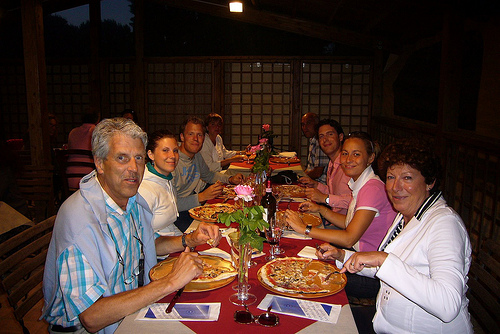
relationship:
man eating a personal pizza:
[38, 115, 224, 333] [158, 254, 237, 284]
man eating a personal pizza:
[175, 113, 246, 204] [214, 181, 247, 198]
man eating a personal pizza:
[294, 106, 328, 178] [275, 151, 302, 166]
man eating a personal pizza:
[299, 118, 352, 206] [274, 181, 312, 201]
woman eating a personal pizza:
[144, 131, 195, 251] [189, 202, 240, 223]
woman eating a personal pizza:
[203, 113, 250, 171] [241, 150, 259, 160]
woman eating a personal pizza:
[286, 130, 399, 252] [275, 207, 321, 229]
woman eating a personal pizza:
[311, 140, 477, 333] [259, 256, 347, 304]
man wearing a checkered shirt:
[38, 115, 224, 333] [43, 189, 164, 329]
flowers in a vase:
[216, 180, 269, 285] [231, 242, 266, 306]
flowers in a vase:
[253, 138, 274, 184] [252, 169, 266, 205]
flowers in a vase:
[261, 123, 274, 145] [268, 141, 271, 161]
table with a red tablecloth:
[112, 150, 363, 334] [157, 230, 350, 333]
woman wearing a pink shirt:
[286, 130, 399, 252] [340, 178, 397, 254]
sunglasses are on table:
[232, 308, 280, 331] [112, 150, 363, 334]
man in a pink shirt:
[299, 118, 352, 206] [309, 156, 356, 208]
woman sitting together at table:
[313, 140, 477, 333] [112, 150, 363, 334]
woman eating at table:
[313, 140, 477, 333] [112, 150, 363, 334]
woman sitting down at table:
[313, 140, 477, 333] [112, 150, 363, 334]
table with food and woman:
[112, 150, 363, 334] [313, 140, 477, 333]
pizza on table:
[158, 254, 237, 284] [112, 150, 363, 334]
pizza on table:
[189, 202, 240, 223] [112, 150, 363, 334]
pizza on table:
[214, 181, 247, 198] [112, 150, 363, 334]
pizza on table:
[259, 256, 347, 304] [112, 150, 363, 334]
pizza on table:
[274, 181, 312, 201] [112, 150, 363, 334]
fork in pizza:
[324, 267, 364, 280] [259, 256, 347, 304]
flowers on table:
[216, 180, 269, 285] [112, 150, 363, 334]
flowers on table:
[253, 138, 274, 184] [112, 150, 363, 334]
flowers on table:
[261, 123, 274, 145] [112, 150, 363, 334]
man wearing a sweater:
[38, 115, 224, 333] [48, 170, 160, 326]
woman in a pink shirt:
[286, 130, 399, 252] [340, 178, 397, 254]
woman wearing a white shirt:
[203, 113, 250, 171] [194, 134, 236, 168]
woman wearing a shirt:
[286, 130, 399, 252] [340, 178, 397, 254]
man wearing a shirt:
[299, 118, 352, 206] [309, 156, 356, 208]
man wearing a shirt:
[38, 115, 224, 333] [43, 189, 164, 329]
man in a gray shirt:
[175, 113, 246, 204] [172, 150, 234, 209]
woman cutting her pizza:
[311, 140, 477, 333] [259, 256, 347, 304]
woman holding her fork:
[311, 140, 477, 333] [324, 267, 364, 280]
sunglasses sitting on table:
[232, 308, 280, 331] [112, 150, 363, 334]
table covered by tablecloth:
[112, 150, 363, 334] [157, 230, 350, 333]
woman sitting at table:
[313, 140, 477, 333] [112, 150, 363, 334]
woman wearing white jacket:
[311, 140, 477, 333] [340, 203, 478, 334]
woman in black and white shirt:
[311, 140, 477, 333] [43, 189, 164, 329]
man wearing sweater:
[38, 115, 224, 333] [48, 170, 160, 326]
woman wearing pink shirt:
[286, 130, 399, 252] [340, 178, 397, 254]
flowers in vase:
[216, 180, 269, 285] [231, 242, 266, 306]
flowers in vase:
[253, 138, 274, 184] [252, 169, 266, 205]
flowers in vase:
[261, 123, 274, 145] [268, 141, 271, 161]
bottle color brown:
[259, 179, 276, 232] [265, 196, 271, 202]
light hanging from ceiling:
[226, 0, 248, 17] [193, 0, 498, 7]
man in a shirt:
[299, 118, 352, 206] [43, 189, 164, 329]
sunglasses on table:
[232, 308, 280, 331] [112, 150, 363, 334]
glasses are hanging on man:
[114, 228, 146, 282] [38, 115, 224, 333]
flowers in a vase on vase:
[216, 180, 269, 285] [231, 242, 266, 306]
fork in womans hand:
[324, 267, 364, 280] [341, 246, 387, 278]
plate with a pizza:
[152, 253, 238, 295] [158, 254, 237, 284]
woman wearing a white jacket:
[311, 140, 477, 333] [340, 203, 478, 334]